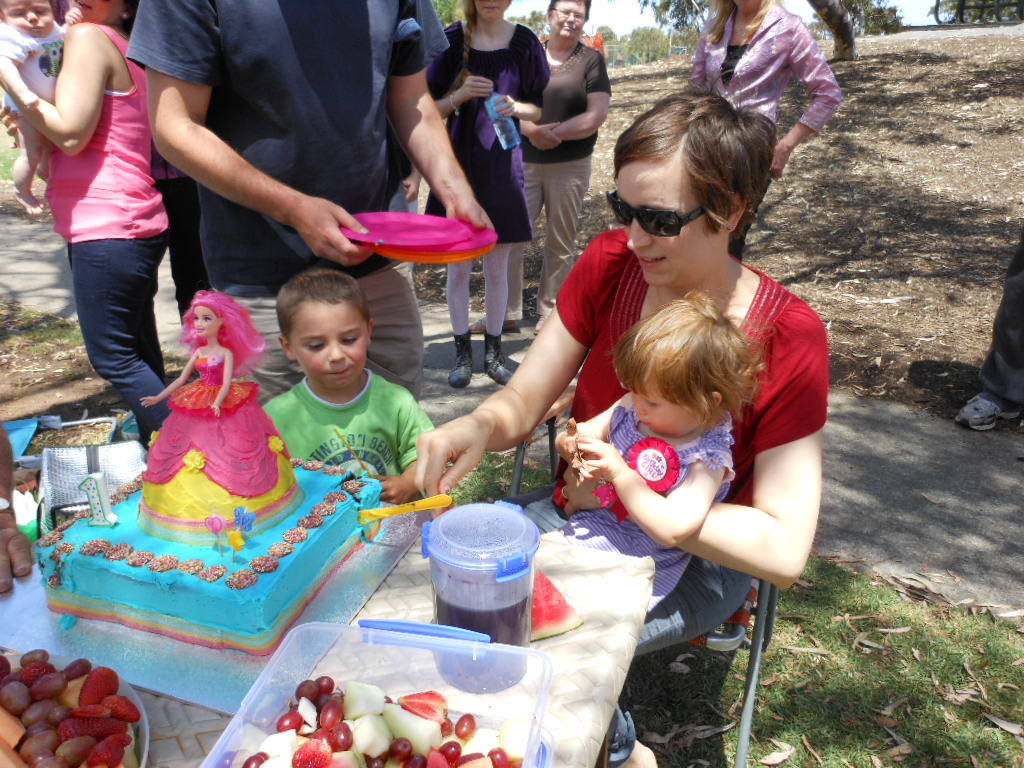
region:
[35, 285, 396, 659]
cake is on the table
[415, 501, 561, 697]
dark juice in container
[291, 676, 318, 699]
red grape in container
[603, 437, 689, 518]
red ribbon on top of shirt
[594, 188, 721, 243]
sunglasses on woman's face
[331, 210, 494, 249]
plate is dark pink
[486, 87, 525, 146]
blue paper in person's hand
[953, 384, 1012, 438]
shoe on top of ground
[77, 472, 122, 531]
green and white candle on top of cake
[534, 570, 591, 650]
watermelon on top of table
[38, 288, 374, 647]
A girls one year birthday cake.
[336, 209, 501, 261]
Pink and orange disposable plates.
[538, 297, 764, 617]
Little girl celebrating her birthday.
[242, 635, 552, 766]
Plastic container holding grapes and melom.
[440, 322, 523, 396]
A woman's black boots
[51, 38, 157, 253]
a womans pink tank shirt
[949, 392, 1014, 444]
a man's tennis shoe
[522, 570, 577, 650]
a slice of watermelon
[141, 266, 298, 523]
A pink hair Barbie doll.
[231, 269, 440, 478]
A small boy with red cheeks.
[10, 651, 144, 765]
A mixed fruits of strawberries and grapes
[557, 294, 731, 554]
A toddler girl held by her mother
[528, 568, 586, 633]
A slice of watermelon on the table.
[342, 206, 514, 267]
Three or more paper plates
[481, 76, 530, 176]
One container of clear water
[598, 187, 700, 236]
A pair of dark shades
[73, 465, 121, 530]
A candle of number One for one year old birthday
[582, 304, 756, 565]
The birthday girl with a ribbon showing her as the birthday girl.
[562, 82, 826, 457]
A lady wearing a red top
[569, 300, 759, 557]
a baby with brown hair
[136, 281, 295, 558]
A doll on a cake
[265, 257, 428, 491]
A little boy in a green shirt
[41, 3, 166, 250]
A person wearing a pink shirt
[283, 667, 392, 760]
A serving of fruit salad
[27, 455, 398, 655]
A cake with blue frosting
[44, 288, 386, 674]
A cake with a doll on it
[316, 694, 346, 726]
A piece of food.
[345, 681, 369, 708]
A piece of food.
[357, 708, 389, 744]
A piece of food.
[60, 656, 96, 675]
A piece of food.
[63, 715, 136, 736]
A piece of food.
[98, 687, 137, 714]
A piece of food.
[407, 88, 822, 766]
a woman sitting in a chair with a baby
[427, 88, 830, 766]
a woman wearing a red shirt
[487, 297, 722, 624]
a baby wearing a ribbon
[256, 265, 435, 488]
a boy in a green shirt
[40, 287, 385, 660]
a blue birthday cake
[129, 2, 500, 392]
a man holding two plates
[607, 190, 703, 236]
a pair of black sun glasses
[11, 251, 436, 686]
barbie doll cake on table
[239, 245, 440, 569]
boy wearing green shirt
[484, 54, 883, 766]
lady wearing red shirt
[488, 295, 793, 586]
little girl sitting on ladies lap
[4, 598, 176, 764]
grapes on strawberries on table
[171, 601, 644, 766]
apples, grapes and strawberries in plastic dish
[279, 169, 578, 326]
man holding pink plates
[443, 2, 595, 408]
girl holding water bottle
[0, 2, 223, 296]
lady holding a baby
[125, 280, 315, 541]
barbie doll on top of cake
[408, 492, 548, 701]
plastic jug of liquid